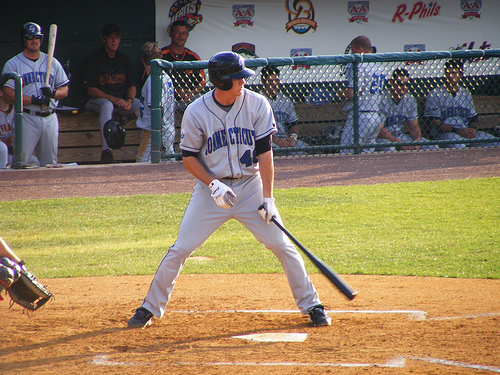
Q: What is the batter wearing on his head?
A: Helmet.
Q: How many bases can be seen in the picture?
A: One.